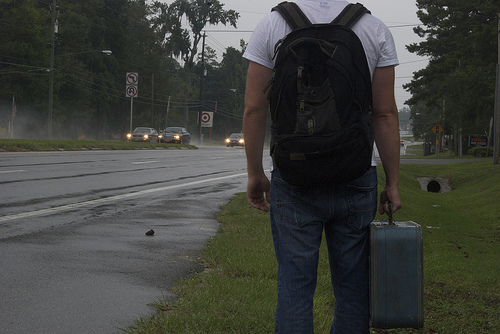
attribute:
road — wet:
[1, 131, 424, 225]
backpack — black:
[268, 1, 374, 191]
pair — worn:
[270, 168, 379, 331]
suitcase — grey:
[375, 220, 423, 323]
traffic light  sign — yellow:
[430, 123, 445, 158]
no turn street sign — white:
[124, 71, 139, 85]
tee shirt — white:
[241, 1, 400, 84]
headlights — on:
[128, 133, 149, 141]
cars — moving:
[125, 124, 245, 152]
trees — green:
[0, 3, 247, 141]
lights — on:
[224, 137, 246, 145]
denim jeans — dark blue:
[261, 167, 378, 332]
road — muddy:
[42, 263, 107, 329]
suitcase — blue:
[366, 194, 424, 331]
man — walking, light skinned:
[235, 3, 407, 331]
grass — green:
[244, 277, 273, 303]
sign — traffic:
[198, 105, 215, 132]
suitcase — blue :
[346, 205, 448, 332]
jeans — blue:
[265, 160, 376, 331]